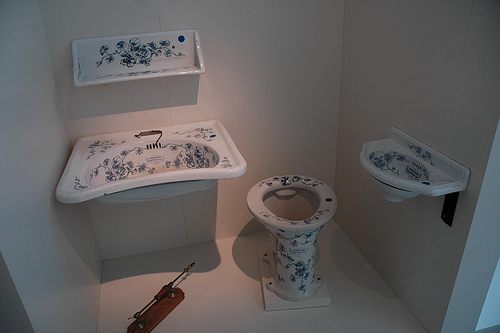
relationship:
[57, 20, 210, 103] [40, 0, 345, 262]
shelf on wall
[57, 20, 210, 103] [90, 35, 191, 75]
shelf has flowers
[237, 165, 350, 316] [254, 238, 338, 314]
toilet has base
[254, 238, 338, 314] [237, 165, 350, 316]
base under toilet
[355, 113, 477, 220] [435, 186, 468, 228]
sink has bracket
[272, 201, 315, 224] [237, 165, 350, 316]
stain in toilet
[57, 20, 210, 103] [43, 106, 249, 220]
shelf above sink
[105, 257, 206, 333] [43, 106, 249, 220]
object under sink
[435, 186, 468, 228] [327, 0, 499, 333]
bracket on wall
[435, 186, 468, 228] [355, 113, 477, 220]
bracket on sink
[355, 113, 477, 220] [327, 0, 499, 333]
sink on wall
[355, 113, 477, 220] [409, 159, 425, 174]
sink has drain holes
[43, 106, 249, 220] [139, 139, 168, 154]
sink has drain holes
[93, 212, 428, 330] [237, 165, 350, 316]
floor under toilet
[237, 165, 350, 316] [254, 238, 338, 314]
toilet on base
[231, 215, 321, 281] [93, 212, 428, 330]
shadow on floor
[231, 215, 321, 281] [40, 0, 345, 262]
shadow on wall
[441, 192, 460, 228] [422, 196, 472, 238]
bracket on wall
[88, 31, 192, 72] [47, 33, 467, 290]
picture on bathroom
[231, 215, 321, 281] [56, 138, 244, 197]
shadow under sink